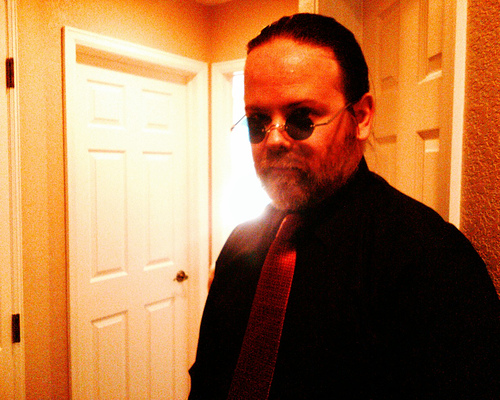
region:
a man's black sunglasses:
[232, 93, 364, 144]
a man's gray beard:
[252, 103, 361, 214]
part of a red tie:
[229, 211, 299, 398]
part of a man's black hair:
[245, 12, 371, 115]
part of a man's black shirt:
[188, 157, 498, 397]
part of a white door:
[75, 55, 190, 397]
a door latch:
[171, 269, 195, 284]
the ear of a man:
[347, 91, 381, 143]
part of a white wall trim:
[436, 0, 466, 230]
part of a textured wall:
[461, 3, 498, 244]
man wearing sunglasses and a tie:
[197, 15, 464, 397]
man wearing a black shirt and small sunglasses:
[189, 23, 420, 398]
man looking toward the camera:
[214, 15, 399, 399]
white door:
[71, 52, 191, 392]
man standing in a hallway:
[185, 12, 487, 399]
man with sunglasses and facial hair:
[191, 10, 482, 395]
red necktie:
[230, 212, 300, 397]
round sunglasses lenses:
[237, 112, 327, 143]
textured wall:
[470, 0, 491, 240]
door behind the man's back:
[377, 0, 451, 169]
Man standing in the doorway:
[187, 21, 498, 398]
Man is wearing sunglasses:
[238, 105, 313, 148]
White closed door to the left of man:
[66, 36, 193, 399]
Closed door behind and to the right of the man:
[333, 3, 454, 205]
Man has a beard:
[251, 150, 354, 211]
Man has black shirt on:
[195, 205, 498, 395]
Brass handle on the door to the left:
[174, 266, 187, 283]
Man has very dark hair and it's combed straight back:
[241, 10, 377, 49]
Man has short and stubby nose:
[260, 131, 293, 154]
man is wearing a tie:
[226, 218, 308, 398]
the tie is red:
[224, 217, 317, 397]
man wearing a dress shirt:
[181, 183, 496, 399]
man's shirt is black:
[182, 180, 497, 394]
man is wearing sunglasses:
[220, 97, 361, 152]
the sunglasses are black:
[221, 103, 361, 157]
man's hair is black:
[242, 11, 394, 176]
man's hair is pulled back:
[238, 0, 386, 104]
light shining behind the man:
[213, 60, 287, 268]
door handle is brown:
[169, 260, 192, 291]